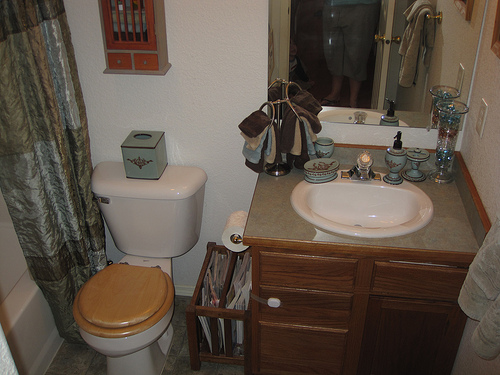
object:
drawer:
[252, 284, 356, 335]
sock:
[290, 115, 318, 156]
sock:
[238, 110, 271, 138]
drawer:
[256, 251, 357, 301]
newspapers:
[231, 251, 249, 295]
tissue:
[119, 130, 168, 180]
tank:
[91, 160, 207, 258]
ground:
[42, 293, 244, 372]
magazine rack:
[183, 241, 257, 374]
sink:
[288, 166, 434, 240]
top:
[242, 142, 480, 252]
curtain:
[0, 1, 108, 346]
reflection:
[317, 1, 376, 108]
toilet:
[70, 159, 208, 375]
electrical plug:
[475, 98, 489, 138]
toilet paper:
[221, 210, 249, 252]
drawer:
[369, 256, 484, 306]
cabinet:
[239, 237, 484, 375]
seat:
[76, 262, 172, 337]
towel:
[276, 106, 322, 153]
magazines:
[234, 294, 246, 359]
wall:
[64, 1, 500, 285]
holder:
[260, 78, 302, 178]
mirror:
[264, 0, 488, 152]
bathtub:
[0, 215, 73, 375]